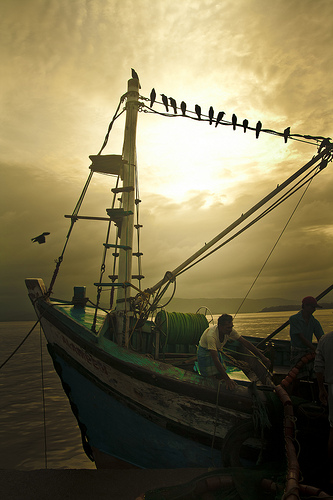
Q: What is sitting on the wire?
A: Birds.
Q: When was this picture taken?
A: Sunset.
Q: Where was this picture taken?
A: On a boat.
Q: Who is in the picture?
A: Two men.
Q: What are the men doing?
A: Steering a boat.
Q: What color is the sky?
A: Golden.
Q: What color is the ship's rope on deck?
A: Green.